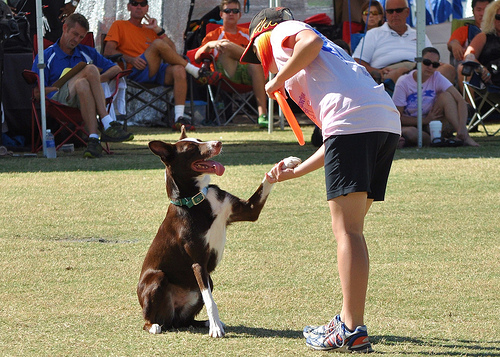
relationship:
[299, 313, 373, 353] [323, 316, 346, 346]
shoes have laces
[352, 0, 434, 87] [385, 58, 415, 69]
man wearing belt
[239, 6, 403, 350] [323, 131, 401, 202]
trainer wearing black pants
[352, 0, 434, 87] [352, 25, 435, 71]
man wearing white top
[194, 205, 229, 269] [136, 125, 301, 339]
chest of dog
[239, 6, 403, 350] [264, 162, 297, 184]
trainer shakes with right hand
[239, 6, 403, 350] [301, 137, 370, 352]
trainer shows left leg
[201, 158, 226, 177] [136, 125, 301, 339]
tongue of dog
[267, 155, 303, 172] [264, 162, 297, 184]
dog's paw in right hand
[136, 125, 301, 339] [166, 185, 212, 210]
dog wears green collar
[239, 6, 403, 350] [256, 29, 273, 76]
trainer has orange hair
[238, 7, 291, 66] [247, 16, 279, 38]
cap has red flames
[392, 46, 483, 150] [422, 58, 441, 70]
woman wears sunglasses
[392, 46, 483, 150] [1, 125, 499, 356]
woman on ground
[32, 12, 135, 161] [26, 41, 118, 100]
man wearing blue shirt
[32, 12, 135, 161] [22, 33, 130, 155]
man in chair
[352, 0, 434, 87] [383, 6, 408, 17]
man wearing dark glasses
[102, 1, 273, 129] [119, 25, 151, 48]
two men in orange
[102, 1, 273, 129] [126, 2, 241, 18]
two men wear sunglasses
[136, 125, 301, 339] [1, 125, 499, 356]
dog on ground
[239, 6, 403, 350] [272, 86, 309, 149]
trainer holds frisbee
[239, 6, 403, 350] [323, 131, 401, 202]
trainer wears black shorts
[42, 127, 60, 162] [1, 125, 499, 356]
bottled water on ground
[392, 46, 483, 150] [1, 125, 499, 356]
woman sitting on ground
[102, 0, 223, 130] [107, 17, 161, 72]
man wearing orange shirt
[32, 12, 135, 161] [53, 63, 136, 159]
man with crossed legs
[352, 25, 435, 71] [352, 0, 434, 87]
white top on man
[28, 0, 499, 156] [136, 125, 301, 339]
spectators watch dog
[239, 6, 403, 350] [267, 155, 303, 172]
trainer hold dog's paw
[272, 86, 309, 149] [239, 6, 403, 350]
frisbee held by trainer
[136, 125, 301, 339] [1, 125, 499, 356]
dog sits on ground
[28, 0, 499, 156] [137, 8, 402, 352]
spectators watch trainer and dog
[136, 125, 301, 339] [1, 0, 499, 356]
dog performs at show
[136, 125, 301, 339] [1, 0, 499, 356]
dog at show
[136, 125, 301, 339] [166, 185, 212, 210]
dog has green collar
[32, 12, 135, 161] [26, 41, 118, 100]
man in blue shirt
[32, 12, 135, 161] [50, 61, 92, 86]
man holds clipboard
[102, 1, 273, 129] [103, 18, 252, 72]
two men in t-shirts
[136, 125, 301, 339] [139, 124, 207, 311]
dog mostly brown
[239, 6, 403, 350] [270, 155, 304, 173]
trainer shakes dog's paw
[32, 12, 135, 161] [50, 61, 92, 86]
man uses clipboard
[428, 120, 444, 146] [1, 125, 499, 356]
white cup on ground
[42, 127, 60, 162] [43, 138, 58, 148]
water bottle with blue lable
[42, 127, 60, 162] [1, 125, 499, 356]
water bottle on ground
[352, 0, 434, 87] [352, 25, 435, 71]
man wears white shirt